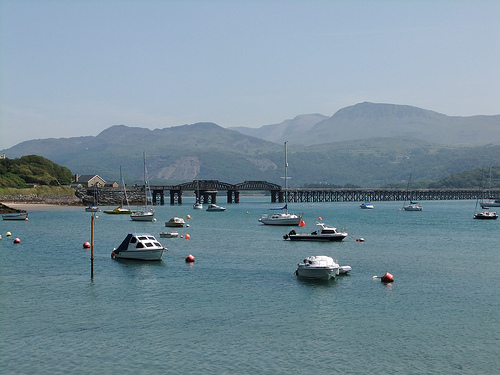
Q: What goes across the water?
A: A bridge.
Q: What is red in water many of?
A: Floaters.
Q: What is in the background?
A: Hills.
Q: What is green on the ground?
A: Grass.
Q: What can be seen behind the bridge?
A: Mountains.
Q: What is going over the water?
A: A long bridge.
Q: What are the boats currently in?
A: Calm body of water.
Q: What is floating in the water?
A: Several boats.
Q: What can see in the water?
A: Boats.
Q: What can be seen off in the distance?
A: Mountains.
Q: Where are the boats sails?
A: They are down.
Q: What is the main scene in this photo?
A: A body of water.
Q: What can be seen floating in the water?
A: Many boats.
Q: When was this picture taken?
A: Morning.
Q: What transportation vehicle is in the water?
A: Boat.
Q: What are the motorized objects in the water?
A: Boats.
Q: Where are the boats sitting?
A: In water.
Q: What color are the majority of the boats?
A: White.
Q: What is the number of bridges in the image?
A: One.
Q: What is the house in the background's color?
A: Brown.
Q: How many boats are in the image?
A: Sixteen.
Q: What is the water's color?
A: Blue.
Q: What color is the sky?
A: Blue.